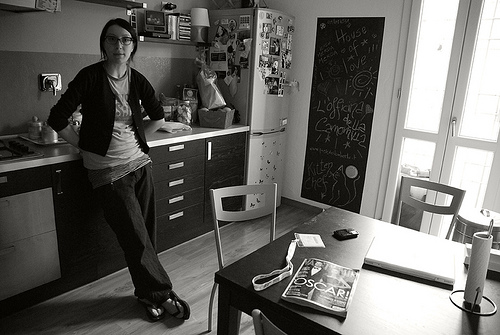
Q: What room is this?
A: It is a kitchen.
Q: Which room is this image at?
A: It is at the kitchen.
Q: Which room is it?
A: It is a kitchen.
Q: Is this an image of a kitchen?
A: Yes, it is showing a kitchen.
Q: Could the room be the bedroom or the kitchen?
A: It is the kitchen.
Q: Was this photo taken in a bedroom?
A: No, the picture was taken in a kitchen.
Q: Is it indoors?
A: Yes, it is indoors.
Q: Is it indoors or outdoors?
A: It is indoors.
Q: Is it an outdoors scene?
A: No, it is indoors.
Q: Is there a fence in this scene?
A: No, there are no fences.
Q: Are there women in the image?
A: Yes, there is a woman.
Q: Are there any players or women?
A: Yes, there is a woman.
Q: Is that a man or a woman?
A: That is a woman.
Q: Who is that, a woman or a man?
A: That is a woman.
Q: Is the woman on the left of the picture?
A: Yes, the woman is on the left of the image.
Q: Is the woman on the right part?
A: No, the woman is on the left of the image.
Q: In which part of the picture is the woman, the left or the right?
A: The woman is on the left of the image.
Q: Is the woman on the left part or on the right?
A: The woman is on the left of the image.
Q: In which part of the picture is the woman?
A: The woman is on the left of the image.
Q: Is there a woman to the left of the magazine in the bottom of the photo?
A: Yes, there is a woman to the left of the magazine.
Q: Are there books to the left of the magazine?
A: No, there is a woman to the left of the magazine.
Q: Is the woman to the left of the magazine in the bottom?
A: Yes, the woman is to the left of the magazine.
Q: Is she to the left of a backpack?
A: No, the woman is to the left of the magazine.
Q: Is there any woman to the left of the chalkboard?
A: Yes, there is a woman to the left of the chalkboard.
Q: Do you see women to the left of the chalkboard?
A: Yes, there is a woman to the left of the chalkboard.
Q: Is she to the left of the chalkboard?
A: Yes, the woman is to the left of the chalkboard.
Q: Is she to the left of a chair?
A: No, the woman is to the left of the chalkboard.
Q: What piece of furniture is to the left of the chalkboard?
A: The piece of furniture is a drawer.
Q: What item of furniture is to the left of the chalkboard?
A: The piece of furniture is a drawer.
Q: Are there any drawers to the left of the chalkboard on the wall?
A: Yes, there is a drawer to the left of the chalkboard.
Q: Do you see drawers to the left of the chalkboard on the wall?
A: Yes, there is a drawer to the left of the chalkboard.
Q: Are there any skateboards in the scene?
A: No, there are no skateboards.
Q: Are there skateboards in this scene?
A: No, there are no skateboards.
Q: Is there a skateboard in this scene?
A: No, there are no skateboards.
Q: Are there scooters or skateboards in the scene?
A: No, there are no skateboards or scooters.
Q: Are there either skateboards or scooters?
A: No, there are no skateboards or scooters.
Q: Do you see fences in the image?
A: No, there are no fences.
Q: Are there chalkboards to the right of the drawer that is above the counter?
A: Yes, there is a chalkboard to the right of the drawer.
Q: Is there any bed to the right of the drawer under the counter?
A: No, there is a chalkboard to the right of the drawer.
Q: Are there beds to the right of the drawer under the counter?
A: No, there is a chalkboard to the right of the drawer.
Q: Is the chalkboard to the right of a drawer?
A: Yes, the chalkboard is to the right of a drawer.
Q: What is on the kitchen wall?
A: The chalkboard is on the wall.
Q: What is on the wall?
A: The chalkboard is on the wall.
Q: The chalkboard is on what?
A: The chalkboard is on the wall.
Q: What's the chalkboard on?
A: The chalkboard is on the wall.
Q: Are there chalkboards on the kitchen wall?
A: Yes, there is a chalkboard on the wall.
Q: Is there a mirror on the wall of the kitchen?
A: No, there is a chalkboard on the wall.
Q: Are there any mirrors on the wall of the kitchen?
A: No, there is a chalkboard on the wall.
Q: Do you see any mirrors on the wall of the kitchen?
A: No, there is a chalkboard on the wall.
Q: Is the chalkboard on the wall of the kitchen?
A: Yes, the chalkboard is on the wall.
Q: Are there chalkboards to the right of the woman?
A: Yes, there is a chalkboard to the right of the woman.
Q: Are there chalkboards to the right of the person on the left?
A: Yes, there is a chalkboard to the right of the woman.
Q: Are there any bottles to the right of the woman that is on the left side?
A: No, there is a chalkboard to the right of the woman.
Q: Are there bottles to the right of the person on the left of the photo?
A: No, there is a chalkboard to the right of the woman.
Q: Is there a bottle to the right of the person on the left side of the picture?
A: No, there is a chalkboard to the right of the woman.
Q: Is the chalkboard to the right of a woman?
A: Yes, the chalkboard is to the right of a woman.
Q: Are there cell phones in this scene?
A: Yes, there is a cell phone.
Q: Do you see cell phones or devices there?
A: Yes, there is a cell phone.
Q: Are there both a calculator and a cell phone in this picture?
A: No, there is a cell phone but no calculators.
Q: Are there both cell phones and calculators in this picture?
A: No, there is a cell phone but no calculators.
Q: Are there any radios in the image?
A: No, there are no radios.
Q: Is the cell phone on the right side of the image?
A: Yes, the cell phone is on the right of the image.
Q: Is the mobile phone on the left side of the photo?
A: No, the mobile phone is on the right of the image.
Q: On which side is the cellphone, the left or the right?
A: The cellphone is on the right of the image.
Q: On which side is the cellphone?
A: The cellphone is on the right of the image.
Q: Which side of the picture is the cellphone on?
A: The cellphone is on the right of the image.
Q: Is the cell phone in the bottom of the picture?
A: Yes, the cell phone is in the bottom of the image.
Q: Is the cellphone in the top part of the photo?
A: No, the cellphone is in the bottom of the image.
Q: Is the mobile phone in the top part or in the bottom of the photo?
A: The mobile phone is in the bottom of the image.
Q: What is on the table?
A: The cell phone is on the table.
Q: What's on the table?
A: The cell phone is on the table.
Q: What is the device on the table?
A: The device is a cell phone.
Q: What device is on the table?
A: The device is a cell phone.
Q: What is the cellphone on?
A: The cellphone is on the table.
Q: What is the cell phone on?
A: The cellphone is on the table.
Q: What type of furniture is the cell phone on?
A: The cell phone is on the table.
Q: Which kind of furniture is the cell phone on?
A: The cell phone is on the table.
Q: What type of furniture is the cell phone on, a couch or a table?
A: The cell phone is on a table.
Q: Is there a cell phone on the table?
A: Yes, there is a cell phone on the table.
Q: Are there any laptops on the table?
A: No, there is a cell phone on the table.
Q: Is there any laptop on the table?
A: No, there is a cell phone on the table.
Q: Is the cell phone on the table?
A: Yes, the cell phone is on the table.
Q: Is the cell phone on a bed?
A: No, the cell phone is on the table.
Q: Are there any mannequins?
A: No, there are no mannequins.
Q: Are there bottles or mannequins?
A: No, there are no mannequins or bottles.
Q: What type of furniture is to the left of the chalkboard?
A: The piece of furniture is a drawer.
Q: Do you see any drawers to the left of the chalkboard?
A: Yes, there is a drawer to the left of the chalkboard.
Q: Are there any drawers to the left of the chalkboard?
A: Yes, there is a drawer to the left of the chalkboard.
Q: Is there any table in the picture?
A: Yes, there is a table.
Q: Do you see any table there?
A: Yes, there is a table.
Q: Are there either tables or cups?
A: Yes, there is a table.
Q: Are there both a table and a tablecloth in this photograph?
A: No, there is a table but no tablecloths.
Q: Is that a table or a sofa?
A: That is a table.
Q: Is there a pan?
A: No, there are no pans.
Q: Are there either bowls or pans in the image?
A: No, there are no pans or bowls.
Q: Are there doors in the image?
A: Yes, there is a door.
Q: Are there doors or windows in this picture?
A: Yes, there is a door.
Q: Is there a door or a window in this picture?
A: Yes, there is a door.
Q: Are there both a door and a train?
A: No, there is a door but no trains.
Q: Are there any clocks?
A: No, there are no clocks.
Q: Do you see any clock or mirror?
A: No, there are no clocks or mirrors.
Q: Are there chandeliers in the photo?
A: No, there are no chandeliers.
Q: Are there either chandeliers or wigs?
A: No, there are no chandeliers or wigs.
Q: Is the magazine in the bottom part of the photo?
A: Yes, the magazine is in the bottom of the image.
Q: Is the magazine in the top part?
A: No, the magazine is in the bottom of the image.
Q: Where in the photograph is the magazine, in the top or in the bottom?
A: The magazine is in the bottom of the image.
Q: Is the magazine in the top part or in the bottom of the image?
A: The magazine is in the bottom of the image.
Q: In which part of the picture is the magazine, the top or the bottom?
A: The magazine is in the bottom of the image.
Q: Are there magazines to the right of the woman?
A: Yes, there is a magazine to the right of the woman.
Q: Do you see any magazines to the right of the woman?
A: Yes, there is a magazine to the right of the woman.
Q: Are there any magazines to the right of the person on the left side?
A: Yes, there is a magazine to the right of the woman.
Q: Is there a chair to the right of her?
A: No, there is a magazine to the right of the woman.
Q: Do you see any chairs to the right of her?
A: No, there is a magazine to the right of the woman.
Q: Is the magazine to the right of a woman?
A: Yes, the magazine is to the right of a woman.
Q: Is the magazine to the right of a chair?
A: No, the magazine is to the right of a woman.